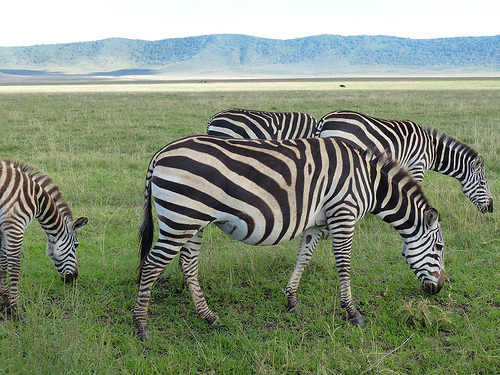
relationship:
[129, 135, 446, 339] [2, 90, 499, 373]
zebra eating grass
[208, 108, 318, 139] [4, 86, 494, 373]
zebra on field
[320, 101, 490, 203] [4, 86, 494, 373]
zebra on field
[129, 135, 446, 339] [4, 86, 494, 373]
zebra on field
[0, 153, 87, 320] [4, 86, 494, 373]
zebra on field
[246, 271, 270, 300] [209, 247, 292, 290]
part of ground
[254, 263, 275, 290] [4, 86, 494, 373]
part of field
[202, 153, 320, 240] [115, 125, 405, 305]
stripes on zebra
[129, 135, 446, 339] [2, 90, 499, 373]
zebra in grass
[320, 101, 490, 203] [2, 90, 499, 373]
zebra in grass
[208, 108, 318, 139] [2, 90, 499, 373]
zebra in grass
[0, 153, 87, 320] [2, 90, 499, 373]
zebra in grass